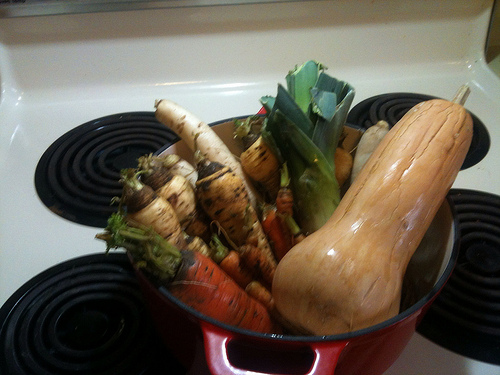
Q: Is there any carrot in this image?
A: Yes, there is a carrot.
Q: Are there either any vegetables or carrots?
A: Yes, there is a carrot.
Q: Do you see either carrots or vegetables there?
A: Yes, there is a carrot.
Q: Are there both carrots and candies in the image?
A: No, there is a carrot but no candies.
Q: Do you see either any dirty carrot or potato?
A: Yes, there is a dirty carrot.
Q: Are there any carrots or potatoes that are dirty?
A: Yes, the carrot is dirty.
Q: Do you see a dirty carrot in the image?
A: Yes, there is a dirty carrot.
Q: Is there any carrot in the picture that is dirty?
A: Yes, there is a carrot that is dirty.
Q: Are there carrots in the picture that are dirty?
A: Yes, there is a carrot that is dirty.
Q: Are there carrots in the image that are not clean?
A: Yes, there is a dirty carrot.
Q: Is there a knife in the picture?
A: No, there are no knives.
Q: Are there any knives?
A: No, there are no knives.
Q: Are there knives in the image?
A: No, there are no knives.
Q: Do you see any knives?
A: No, there are no knives.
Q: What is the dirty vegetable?
A: The vegetable is a carrot.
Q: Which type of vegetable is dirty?
A: The vegetable is a carrot.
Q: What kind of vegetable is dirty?
A: The vegetable is a carrot.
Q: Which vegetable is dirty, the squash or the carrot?
A: The carrot is dirty.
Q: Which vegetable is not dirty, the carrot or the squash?
A: The squash is not dirty.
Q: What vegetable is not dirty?
A: The vegetable is a squash.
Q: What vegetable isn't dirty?
A: The vegetable is a squash.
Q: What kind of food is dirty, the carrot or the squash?
A: The carrot is dirty.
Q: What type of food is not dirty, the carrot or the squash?
A: The squash is not dirty.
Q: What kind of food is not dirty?
A: The food is a squash.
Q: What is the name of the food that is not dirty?
A: The food is a squash.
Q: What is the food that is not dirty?
A: The food is a squash.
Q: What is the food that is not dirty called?
A: The food is a squash.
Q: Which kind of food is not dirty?
A: The food is a squash.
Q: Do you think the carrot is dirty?
A: Yes, the carrot is dirty.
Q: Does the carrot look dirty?
A: Yes, the carrot is dirty.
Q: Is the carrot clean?
A: No, the carrot is dirty.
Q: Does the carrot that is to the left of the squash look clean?
A: No, the carrot is dirty.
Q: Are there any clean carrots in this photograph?
A: No, there is a carrot but it is dirty.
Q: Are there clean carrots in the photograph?
A: No, there is a carrot but it is dirty.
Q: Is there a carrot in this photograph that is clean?
A: No, there is a carrot but it is dirty.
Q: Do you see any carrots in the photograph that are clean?
A: No, there is a carrot but it is dirty.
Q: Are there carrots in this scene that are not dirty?
A: No, there is a carrot but it is dirty.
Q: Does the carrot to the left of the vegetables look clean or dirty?
A: The carrot is dirty.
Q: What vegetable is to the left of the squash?
A: The vegetable is a carrot.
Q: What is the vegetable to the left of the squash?
A: The vegetable is a carrot.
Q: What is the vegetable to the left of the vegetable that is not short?
A: The vegetable is a carrot.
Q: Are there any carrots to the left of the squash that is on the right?
A: Yes, there is a carrot to the left of the squash.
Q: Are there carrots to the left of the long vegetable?
A: Yes, there is a carrot to the left of the squash.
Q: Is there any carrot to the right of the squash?
A: No, the carrot is to the left of the squash.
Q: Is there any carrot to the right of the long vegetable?
A: No, the carrot is to the left of the squash.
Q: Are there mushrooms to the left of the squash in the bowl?
A: No, there is a carrot to the left of the squash.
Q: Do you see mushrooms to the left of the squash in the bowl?
A: No, there is a carrot to the left of the squash.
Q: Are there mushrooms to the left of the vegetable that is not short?
A: No, there is a carrot to the left of the squash.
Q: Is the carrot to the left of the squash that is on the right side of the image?
A: Yes, the carrot is to the left of the squash.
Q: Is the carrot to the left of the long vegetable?
A: Yes, the carrot is to the left of the squash.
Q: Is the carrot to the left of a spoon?
A: No, the carrot is to the left of the squash.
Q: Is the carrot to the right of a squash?
A: No, the carrot is to the left of a squash.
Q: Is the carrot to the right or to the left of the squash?
A: The carrot is to the left of the squash.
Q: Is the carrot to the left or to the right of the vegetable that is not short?
A: The carrot is to the left of the squash.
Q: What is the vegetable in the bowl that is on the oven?
A: The vegetable is a carrot.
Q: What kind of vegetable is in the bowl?
A: The vegetable is a carrot.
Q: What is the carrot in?
A: The carrot is in the bowl.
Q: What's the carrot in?
A: The carrot is in the bowl.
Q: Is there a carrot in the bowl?
A: Yes, there is a carrot in the bowl.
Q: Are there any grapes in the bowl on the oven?
A: No, there is a carrot in the bowl.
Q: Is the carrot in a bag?
A: No, the carrot is in a bowl.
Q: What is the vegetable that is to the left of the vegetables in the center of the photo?
A: The vegetable is a carrot.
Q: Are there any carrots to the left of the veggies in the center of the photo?
A: Yes, there is a carrot to the left of the vegetables.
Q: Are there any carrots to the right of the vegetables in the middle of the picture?
A: No, the carrot is to the left of the vegetables.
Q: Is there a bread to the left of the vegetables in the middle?
A: No, there is a carrot to the left of the vegetables.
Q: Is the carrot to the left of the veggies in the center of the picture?
A: Yes, the carrot is to the left of the vegetables.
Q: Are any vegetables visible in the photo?
A: Yes, there are vegetables.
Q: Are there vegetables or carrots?
A: Yes, there are vegetables.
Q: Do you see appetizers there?
A: No, there are no appetizers.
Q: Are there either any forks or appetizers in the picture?
A: No, there are no appetizers or forks.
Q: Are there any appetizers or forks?
A: No, there are no appetizers or forks.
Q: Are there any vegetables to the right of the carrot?
A: Yes, there are vegetables to the right of the carrot.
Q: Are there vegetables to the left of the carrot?
A: No, the vegetables are to the right of the carrot.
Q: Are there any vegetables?
A: Yes, there are vegetables.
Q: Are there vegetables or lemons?
A: Yes, there are vegetables.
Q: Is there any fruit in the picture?
A: No, there are no fruits.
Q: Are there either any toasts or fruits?
A: No, there are no fruits or toasts.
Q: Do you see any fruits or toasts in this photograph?
A: No, there are no fruits or toasts.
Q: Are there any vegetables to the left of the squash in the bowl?
A: Yes, there are vegetables to the left of the squash.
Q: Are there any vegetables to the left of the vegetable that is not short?
A: Yes, there are vegetables to the left of the squash.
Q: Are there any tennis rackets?
A: No, there are no tennis rackets.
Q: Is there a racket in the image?
A: No, there are no rackets.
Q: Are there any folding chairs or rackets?
A: No, there are no rackets or folding chairs.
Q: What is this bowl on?
A: The bowl is on the oven.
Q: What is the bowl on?
A: The bowl is on the oven.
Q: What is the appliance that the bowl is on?
A: The appliance is an oven.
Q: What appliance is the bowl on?
A: The bowl is on the oven.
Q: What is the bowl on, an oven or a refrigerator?
A: The bowl is on an oven.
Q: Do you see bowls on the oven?
A: Yes, there is a bowl on the oven.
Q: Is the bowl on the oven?
A: Yes, the bowl is on the oven.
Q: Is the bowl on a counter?
A: No, the bowl is on the oven.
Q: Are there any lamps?
A: No, there are no lamps.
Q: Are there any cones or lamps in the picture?
A: No, there are no lamps or cones.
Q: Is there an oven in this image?
A: Yes, there is an oven.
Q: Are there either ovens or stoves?
A: Yes, there is an oven.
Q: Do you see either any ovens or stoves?
A: Yes, there is an oven.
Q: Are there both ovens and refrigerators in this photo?
A: No, there is an oven but no refrigerators.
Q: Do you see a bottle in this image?
A: No, there are no bottles.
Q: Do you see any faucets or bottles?
A: No, there are no bottles or faucets.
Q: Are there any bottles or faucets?
A: No, there are no bottles or faucets.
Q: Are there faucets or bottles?
A: No, there are no bottles or faucets.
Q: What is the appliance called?
A: The appliance is an oven.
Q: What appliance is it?
A: The appliance is an oven.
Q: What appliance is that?
A: This is an oven.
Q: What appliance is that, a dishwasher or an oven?
A: This is an oven.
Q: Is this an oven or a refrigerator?
A: This is an oven.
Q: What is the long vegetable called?
A: The vegetable is a squash.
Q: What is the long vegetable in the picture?
A: The vegetable is a squash.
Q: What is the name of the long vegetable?
A: The vegetable is a squash.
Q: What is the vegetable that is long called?
A: The vegetable is a squash.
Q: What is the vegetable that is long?
A: The vegetable is a squash.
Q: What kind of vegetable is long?
A: The vegetable is a squash.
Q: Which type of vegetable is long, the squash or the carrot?
A: The squash is long.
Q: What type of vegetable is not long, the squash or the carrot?
A: The carrot is not long.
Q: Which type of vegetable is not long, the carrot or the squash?
A: The carrot is not long.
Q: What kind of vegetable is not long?
A: The vegetable is a carrot.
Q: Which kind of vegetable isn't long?
A: The vegetable is a carrot.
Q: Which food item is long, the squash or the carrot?
A: The squash is long.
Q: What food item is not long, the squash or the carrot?
A: The carrot is not long.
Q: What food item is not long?
A: The food item is a carrot.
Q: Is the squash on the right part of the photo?
A: Yes, the squash is on the right of the image.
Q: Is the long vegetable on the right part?
A: Yes, the squash is on the right of the image.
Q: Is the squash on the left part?
A: No, the squash is on the right of the image.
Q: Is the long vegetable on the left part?
A: No, the squash is on the right of the image.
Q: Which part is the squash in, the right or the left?
A: The squash is on the right of the image.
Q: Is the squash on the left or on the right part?
A: The squash is on the right of the image.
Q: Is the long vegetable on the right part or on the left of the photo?
A: The squash is on the right of the image.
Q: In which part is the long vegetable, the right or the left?
A: The squash is on the right of the image.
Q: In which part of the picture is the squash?
A: The squash is on the right of the image.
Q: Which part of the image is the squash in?
A: The squash is on the right of the image.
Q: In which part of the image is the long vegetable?
A: The squash is on the right of the image.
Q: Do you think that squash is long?
A: Yes, the squash is long.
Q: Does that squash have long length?
A: Yes, the squash is long.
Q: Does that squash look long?
A: Yes, the squash is long.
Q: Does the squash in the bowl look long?
A: Yes, the squash is long.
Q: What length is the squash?
A: The squash is long.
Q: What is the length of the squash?
A: The squash is long.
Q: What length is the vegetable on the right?
A: The squash is long.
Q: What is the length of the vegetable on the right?
A: The squash is long.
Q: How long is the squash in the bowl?
A: The squash is long.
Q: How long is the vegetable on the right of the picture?
A: The squash is long.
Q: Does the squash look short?
A: No, the squash is long.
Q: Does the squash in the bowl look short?
A: No, the squash is long.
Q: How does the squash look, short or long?
A: The squash is long.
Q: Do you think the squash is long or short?
A: The squash is long.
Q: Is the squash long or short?
A: The squash is long.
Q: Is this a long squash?
A: Yes, this is a long squash.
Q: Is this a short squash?
A: No, this is a long squash.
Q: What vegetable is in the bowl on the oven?
A: The vegetable is a squash.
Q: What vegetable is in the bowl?
A: The vegetable is a squash.